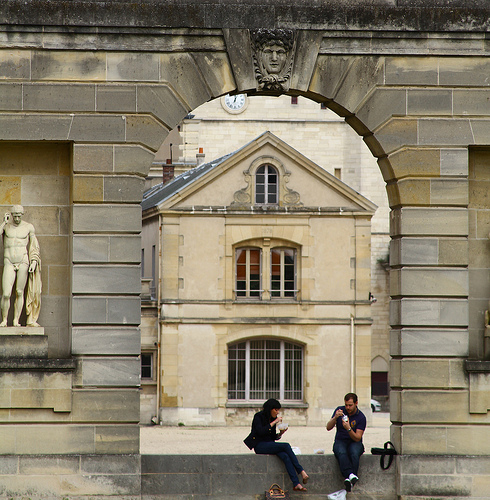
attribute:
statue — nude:
[1, 204, 50, 325]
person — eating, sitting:
[243, 395, 312, 492]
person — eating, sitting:
[328, 393, 370, 492]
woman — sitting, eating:
[245, 394, 310, 497]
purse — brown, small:
[255, 481, 290, 498]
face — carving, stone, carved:
[249, 23, 291, 87]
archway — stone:
[134, 86, 412, 491]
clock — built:
[215, 95, 253, 118]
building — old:
[139, 90, 392, 430]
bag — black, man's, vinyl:
[369, 439, 403, 473]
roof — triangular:
[147, 133, 379, 207]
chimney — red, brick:
[160, 140, 178, 184]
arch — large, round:
[140, 85, 405, 210]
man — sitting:
[329, 394, 371, 489]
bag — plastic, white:
[323, 486, 346, 498]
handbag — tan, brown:
[259, 482, 287, 498]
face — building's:
[143, 89, 392, 430]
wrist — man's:
[346, 423, 352, 431]